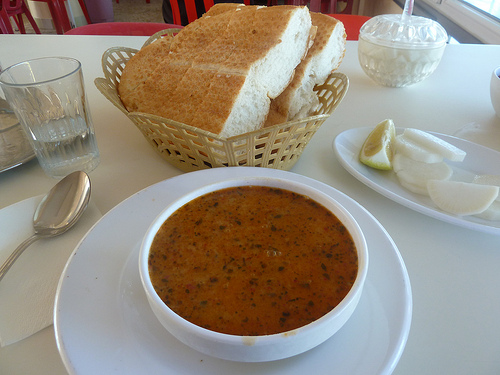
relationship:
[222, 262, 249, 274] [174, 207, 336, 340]
seasonings in soup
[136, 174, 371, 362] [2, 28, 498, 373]
bowl on table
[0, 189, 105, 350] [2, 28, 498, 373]
napkin on table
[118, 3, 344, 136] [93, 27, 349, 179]
bread on breadbasket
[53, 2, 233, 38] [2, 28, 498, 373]
chair at table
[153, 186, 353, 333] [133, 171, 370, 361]
soup in white bowl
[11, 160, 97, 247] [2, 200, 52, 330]
silver spoon on white napkin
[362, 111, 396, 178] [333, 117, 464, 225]
lemon on plate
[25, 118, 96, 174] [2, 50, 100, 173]
water in glass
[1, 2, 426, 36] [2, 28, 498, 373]
red chairs at table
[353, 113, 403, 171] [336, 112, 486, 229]
slice on plate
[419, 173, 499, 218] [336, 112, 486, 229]
slice on plate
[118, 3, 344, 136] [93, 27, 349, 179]
bread in breadbasket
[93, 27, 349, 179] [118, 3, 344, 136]
breadbasket of bread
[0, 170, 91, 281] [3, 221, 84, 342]
silver spoon sitting on napkin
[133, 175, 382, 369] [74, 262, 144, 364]
bowl sitting on plate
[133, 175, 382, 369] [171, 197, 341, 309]
bowl of soup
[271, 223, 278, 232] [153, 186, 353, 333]
herb floating in soup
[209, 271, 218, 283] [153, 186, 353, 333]
herb floating in soup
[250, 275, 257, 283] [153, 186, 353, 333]
herb floating in soup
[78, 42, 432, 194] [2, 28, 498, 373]
breadbasket sitting on table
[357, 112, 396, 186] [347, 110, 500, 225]
lemon wedge on plate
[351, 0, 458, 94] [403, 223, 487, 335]
container on table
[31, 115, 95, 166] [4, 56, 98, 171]
water in cup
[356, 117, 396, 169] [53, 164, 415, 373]
lemon on plate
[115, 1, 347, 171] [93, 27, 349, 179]
bread in breadbasket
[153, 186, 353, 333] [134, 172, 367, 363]
soup in bowl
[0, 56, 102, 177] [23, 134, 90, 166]
cup of water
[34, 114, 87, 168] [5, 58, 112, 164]
water in glass